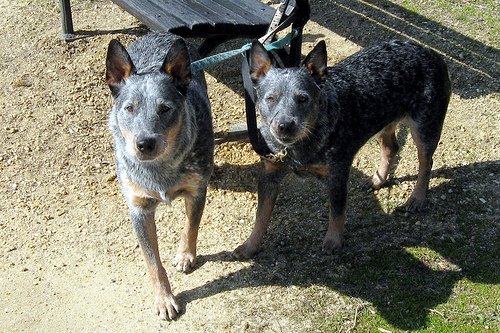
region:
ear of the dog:
[307, 42, 325, 74]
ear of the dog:
[243, 48, 273, 75]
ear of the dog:
[167, 45, 195, 79]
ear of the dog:
[92, 29, 129, 82]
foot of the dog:
[145, 283, 185, 324]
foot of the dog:
[177, 255, 197, 276]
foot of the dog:
[242, 238, 266, 268]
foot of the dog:
[322, 230, 360, 256]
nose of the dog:
[273, 115, 298, 134]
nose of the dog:
[136, 133, 158, 155]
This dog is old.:
[101, 28, 229, 320]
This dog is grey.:
[244, 28, 457, 256]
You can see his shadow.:
[165, 138, 473, 325]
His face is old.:
[101, 39, 192, 161]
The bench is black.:
[68, 0, 310, 72]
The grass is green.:
[347, 244, 488, 329]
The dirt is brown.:
[24, 71, 86, 280]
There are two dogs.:
[81, 15, 474, 321]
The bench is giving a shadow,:
[310, 3, 498, 104]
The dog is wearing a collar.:
[276, 133, 296, 160]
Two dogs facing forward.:
[85, 15, 455, 324]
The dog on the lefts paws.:
[144, 245, 206, 320]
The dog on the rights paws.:
[232, 233, 343, 265]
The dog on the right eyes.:
[261, 82, 308, 111]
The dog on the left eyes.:
[120, 95, 177, 128]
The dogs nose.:
[137, 138, 155, 153]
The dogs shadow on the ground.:
[360, 158, 497, 323]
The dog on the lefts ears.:
[97, 40, 194, 86]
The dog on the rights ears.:
[245, 40, 331, 81]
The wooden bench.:
[85, 0, 294, 40]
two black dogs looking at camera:
[88, 15, 463, 332]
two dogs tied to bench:
[97, 18, 454, 325]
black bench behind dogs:
[61, 0, 317, 160]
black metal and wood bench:
[63, 0, 313, 160]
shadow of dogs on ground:
[165, 141, 495, 331]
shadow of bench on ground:
[280, 0, 496, 100]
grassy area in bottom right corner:
[260, 187, 497, 332]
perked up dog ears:
[242, 33, 332, 92]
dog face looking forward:
[103, 65, 191, 170]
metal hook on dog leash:
[257, 144, 291, 167]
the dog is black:
[401, 51, 422, 70]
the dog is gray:
[140, 85, 152, 103]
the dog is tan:
[127, 185, 139, 204]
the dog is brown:
[311, 162, 327, 175]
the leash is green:
[209, 50, 231, 62]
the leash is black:
[238, 99, 257, 119]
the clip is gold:
[268, 147, 290, 163]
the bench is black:
[173, 10, 225, 26]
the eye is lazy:
[264, 92, 277, 105]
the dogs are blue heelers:
[94, 34, 339, 171]